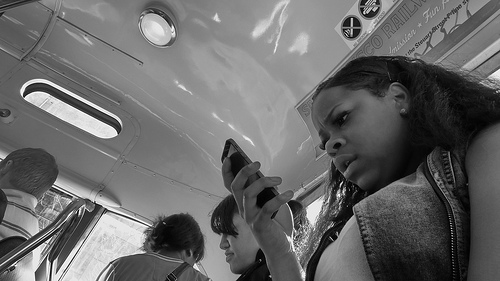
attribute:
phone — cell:
[220, 139, 278, 219]